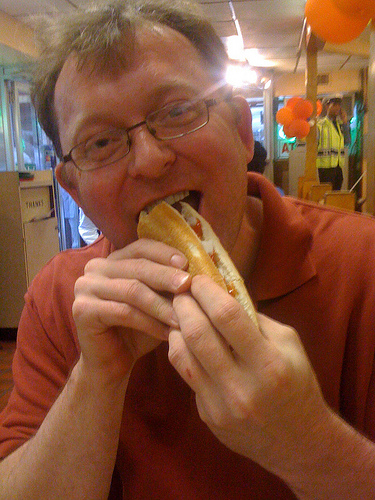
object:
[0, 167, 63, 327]
container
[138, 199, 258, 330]
bun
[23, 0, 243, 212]
hair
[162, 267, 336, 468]
hand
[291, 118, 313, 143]
balloons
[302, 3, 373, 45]
balloons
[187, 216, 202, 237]
ketchup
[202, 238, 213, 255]
onion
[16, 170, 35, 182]
trays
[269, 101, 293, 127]
balloons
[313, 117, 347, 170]
vest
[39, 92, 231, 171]
glasses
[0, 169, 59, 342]
trash can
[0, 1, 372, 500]
restaurant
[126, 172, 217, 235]
mouth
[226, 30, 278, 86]
light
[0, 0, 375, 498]
man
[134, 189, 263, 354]
hot dog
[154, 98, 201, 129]
eye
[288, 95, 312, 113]
balloons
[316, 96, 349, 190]
man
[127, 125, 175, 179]
nose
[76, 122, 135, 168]
eye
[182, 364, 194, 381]
cut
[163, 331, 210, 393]
finger